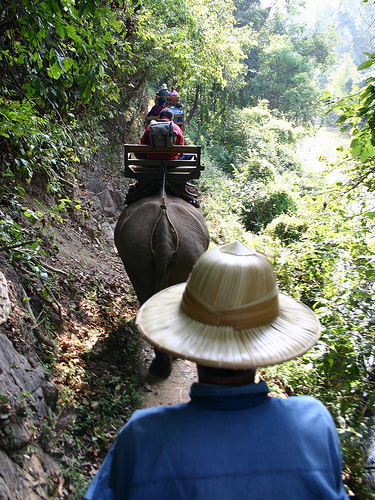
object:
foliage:
[0, 0, 252, 190]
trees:
[257, 32, 336, 126]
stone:
[0, 327, 66, 498]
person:
[79, 238, 350, 500]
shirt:
[78, 377, 350, 498]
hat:
[135, 238, 322, 369]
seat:
[154, 96, 181, 106]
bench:
[123, 142, 205, 181]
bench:
[144, 113, 186, 133]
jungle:
[200, 2, 373, 228]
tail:
[152, 235, 173, 297]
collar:
[149, 197, 179, 256]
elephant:
[113, 182, 210, 381]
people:
[147, 94, 171, 117]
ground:
[0, 0, 375, 500]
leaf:
[356, 57, 374, 71]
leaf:
[55, 25, 66, 39]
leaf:
[105, 21, 119, 32]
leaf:
[326, 356, 334, 367]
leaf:
[73, 203, 83, 211]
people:
[140, 107, 185, 160]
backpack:
[149, 119, 179, 152]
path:
[31, 82, 262, 500]